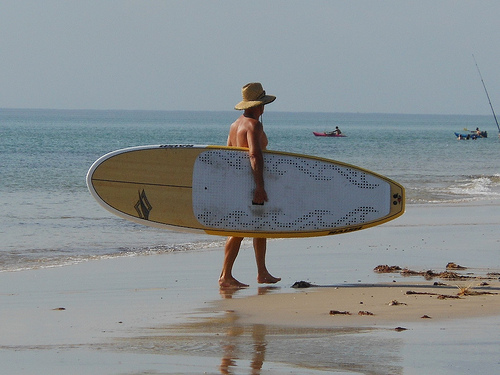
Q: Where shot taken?
A: Beach.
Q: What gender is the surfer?
A: Male.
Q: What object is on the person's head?
A: Hat.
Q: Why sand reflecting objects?
A: Wet.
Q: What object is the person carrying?
A: Surfboard.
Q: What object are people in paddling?
A: Kayak.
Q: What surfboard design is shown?
A: White, black, and wood.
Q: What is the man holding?
A: Surfboard.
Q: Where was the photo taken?
A: Beach.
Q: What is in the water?
A: Boats.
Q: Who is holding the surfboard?
A: Man with hat.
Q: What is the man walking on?
A: The beach.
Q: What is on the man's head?
A: Hat.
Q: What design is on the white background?
A: Black waves.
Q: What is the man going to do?
A: Go surfing.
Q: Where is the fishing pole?
A: In front of water.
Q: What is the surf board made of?
A: Wood.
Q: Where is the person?
A: On the beach.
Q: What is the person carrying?
A: A surfboard.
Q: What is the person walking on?
A: The sand.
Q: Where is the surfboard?
A: In the man's hands.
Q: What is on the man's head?
A: A hat.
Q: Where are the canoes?
A: In the ocean.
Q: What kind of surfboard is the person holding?
A: Longboard.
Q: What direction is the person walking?
A: Towards the right.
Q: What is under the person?
A: Sand.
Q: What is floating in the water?
A: Canoes.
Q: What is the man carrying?
A: Surfboard.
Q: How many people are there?
A: One.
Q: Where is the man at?
A: Beach.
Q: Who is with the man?
A: No one.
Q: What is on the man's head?
A: Hat.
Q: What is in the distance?
A: Boats.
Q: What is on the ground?
A: Sand.